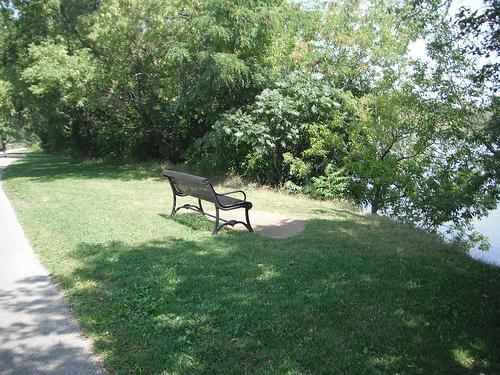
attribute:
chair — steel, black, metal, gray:
[151, 165, 258, 220]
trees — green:
[164, 72, 201, 114]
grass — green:
[68, 202, 133, 241]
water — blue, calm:
[483, 219, 497, 230]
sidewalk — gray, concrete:
[7, 248, 35, 260]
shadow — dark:
[109, 161, 139, 174]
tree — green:
[66, 72, 85, 98]